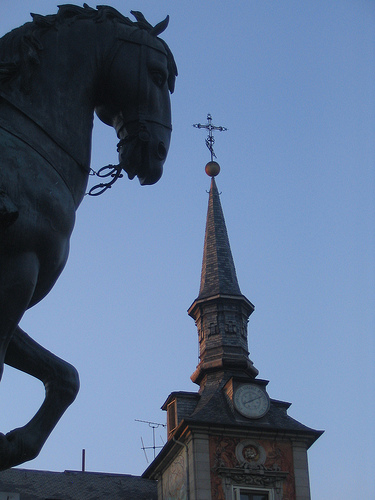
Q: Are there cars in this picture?
A: No, there are no cars.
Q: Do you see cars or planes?
A: No, there are no cars or planes.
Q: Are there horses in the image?
A: Yes, there is a horse.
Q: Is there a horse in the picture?
A: Yes, there is a horse.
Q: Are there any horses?
A: Yes, there is a horse.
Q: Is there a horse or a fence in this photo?
A: Yes, there is a horse.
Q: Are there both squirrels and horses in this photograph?
A: No, there is a horse but no squirrels.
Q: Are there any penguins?
A: No, there are no penguins.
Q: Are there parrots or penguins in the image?
A: No, there are no penguins or parrots.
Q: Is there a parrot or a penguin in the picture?
A: No, there are no penguins or parrots.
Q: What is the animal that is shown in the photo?
A: The animal is a horse.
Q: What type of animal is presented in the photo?
A: The animal is a horse.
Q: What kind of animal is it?
A: The animal is a horse.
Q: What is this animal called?
A: This is a horse.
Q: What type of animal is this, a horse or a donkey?
A: This is a horse.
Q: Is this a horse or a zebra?
A: This is a horse.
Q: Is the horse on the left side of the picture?
A: Yes, the horse is on the left of the image.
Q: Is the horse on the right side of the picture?
A: No, the horse is on the left of the image.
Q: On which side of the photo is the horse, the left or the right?
A: The horse is on the left of the image.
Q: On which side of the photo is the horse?
A: The horse is on the left of the image.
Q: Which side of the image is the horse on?
A: The horse is on the left of the image.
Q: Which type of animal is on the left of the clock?
A: The animal is a horse.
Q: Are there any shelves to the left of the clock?
A: No, there is a horse to the left of the clock.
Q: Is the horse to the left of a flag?
A: No, the horse is to the left of the clock.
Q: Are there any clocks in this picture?
A: Yes, there is a clock.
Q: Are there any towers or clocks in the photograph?
A: Yes, there is a clock.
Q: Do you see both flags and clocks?
A: No, there is a clock but no flags.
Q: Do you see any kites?
A: No, there are no kites.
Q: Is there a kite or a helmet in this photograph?
A: No, there are no kites or helmets.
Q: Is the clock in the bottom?
A: Yes, the clock is in the bottom of the image.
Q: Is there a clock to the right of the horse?
A: Yes, there is a clock to the right of the horse.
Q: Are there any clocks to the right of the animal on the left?
A: Yes, there is a clock to the right of the horse.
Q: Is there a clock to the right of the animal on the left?
A: Yes, there is a clock to the right of the horse.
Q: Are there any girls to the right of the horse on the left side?
A: No, there is a clock to the right of the horse.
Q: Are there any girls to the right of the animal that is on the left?
A: No, there is a clock to the right of the horse.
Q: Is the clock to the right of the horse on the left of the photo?
A: Yes, the clock is to the right of the horse.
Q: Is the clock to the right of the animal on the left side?
A: Yes, the clock is to the right of the horse.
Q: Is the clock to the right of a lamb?
A: No, the clock is to the right of the horse.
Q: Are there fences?
A: No, there are no fences.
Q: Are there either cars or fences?
A: No, there are no fences or cars.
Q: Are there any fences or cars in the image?
A: No, there are no fences or cars.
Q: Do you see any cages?
A: No, there are no cages.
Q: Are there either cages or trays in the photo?
A: No, there are no cages or trays.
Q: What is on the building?
A: The cross is on the building.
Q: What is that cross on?
A: The cross is on the building.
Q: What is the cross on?
A: The cross is on the building.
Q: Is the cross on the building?
A: Yes, the cross is on the building.